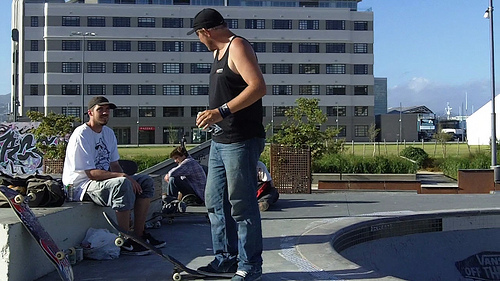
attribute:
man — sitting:
[66, 96, 166, 251]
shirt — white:
[60, 125, 125, 188]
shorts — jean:
[80, 177, 156, 208]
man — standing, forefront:
[185, 8, 276, 280]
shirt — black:
[205, 36, 270, 141]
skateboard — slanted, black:
[101, 214, 205, 280]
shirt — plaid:
[168, 161, 209, 197]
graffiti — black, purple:
[2, 127, 54, 170]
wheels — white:
[16, 192, 75, 257]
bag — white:
[82, 226, 122, 260]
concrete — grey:
[28, 161, 494, 274]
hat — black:
[185, 12, 229, 34]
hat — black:
[89, 95, 116, 109]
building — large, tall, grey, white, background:
[14, 4, 376, 144]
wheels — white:
[112, 236, 181, 281]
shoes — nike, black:
[117, 232, 166, 255]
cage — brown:
[271, 143, 313, 194]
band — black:
[219, 104, 233, 119]